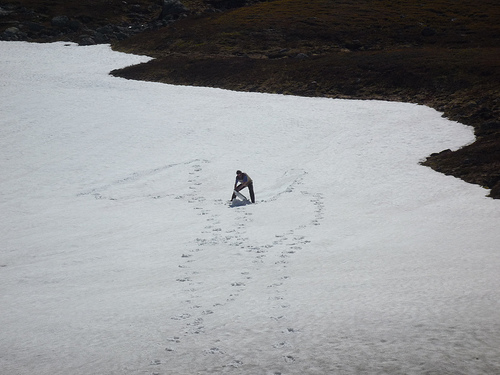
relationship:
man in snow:
[217, 160, 272, 205] [66, 109, 123, 131]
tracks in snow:
[294, 187, 323, 277] [66, 109, 123, 131]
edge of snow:
[281, 84, 386, 118] [66, 109, 123, 131]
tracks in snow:
[219, 211, 309, 288] [66, 109, 123, 131]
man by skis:
[217, 160, 272, 205] [233, 188, 252, 205]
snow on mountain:
[66, 109, 123, 131] [458, 120, 494, 167]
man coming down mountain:
[217, 160, 272, 205] [458, 120, 494, 167]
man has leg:
[217, 160, 272, 205] [233, 184, 243, 194]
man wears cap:
[217, 160, 272, 205] [231, 160, 253, 177]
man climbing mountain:
[217, 160, 272, 205] [458, 120, 494, 167]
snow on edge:
[66, 109, 123, 131] [281, 84, 386, 118]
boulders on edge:
[61, 17, 114, 45] [281, 84, 386, 118]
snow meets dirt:
[66, 109, 123, 131] [204, 70, 227, 106]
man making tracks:
[217, 160, 272, 205] [294, 187, 323, 277]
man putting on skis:
[217, 160, 272, 205] [233, 188, 252, 205]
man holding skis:
[217, 160, 272, 205] [227, 186, 262, 219]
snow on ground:
[66, 109, 123, 131] [10, 83, 37, 97]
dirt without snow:
[204, 70, 227, 106] [66, 109, 123, 131]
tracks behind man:
[294, 187, 323, 277] [217, 160, 272, 205]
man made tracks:
[217, 160, 272, 205] [294, 187, 323, 277]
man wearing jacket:
[217, 160, 272, 205] [239, 175, 247, 186]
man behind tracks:
[217, 160, 272, 205] [294, 187, 323, 277]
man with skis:
[217, 160, 272, 205] [227, 186, 262, 219]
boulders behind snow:
[61, 17, 114, 45] [66, 109, 123, 131]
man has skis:
[217, 160, 272, 205] [227, 186, 262, 219]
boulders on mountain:
[61, 17, 114, 45] [458, 120, 494, 167]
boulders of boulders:
[61, 27, 113, 41] [61, 17, 114, 45]